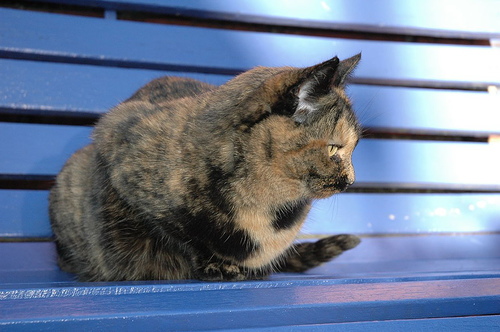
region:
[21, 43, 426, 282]
cat sitting on a bench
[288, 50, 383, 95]
two pointy ears on the head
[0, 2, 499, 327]
blue paint on the bench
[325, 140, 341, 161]
small yellow eye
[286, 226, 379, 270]
black stripes on the tail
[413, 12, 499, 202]
light shining on the bench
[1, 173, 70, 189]
space between the wooden slabs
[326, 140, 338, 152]
black line on the eyeball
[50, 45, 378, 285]
cat's body is covered in fur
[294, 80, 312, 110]
light hair in the ear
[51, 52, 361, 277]
a cat is sitting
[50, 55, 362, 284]
the cat is furry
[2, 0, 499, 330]
the bench is wood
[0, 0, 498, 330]
bench is painted blue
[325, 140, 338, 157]
eye of a cat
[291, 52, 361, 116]
ears are pointed forward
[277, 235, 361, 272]
tail of a cat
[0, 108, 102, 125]
gap in the bench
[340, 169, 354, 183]
nose of a cat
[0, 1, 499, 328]
A blue bench with a cat sitting on it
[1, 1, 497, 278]
The back support of the bench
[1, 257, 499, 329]
The seat of the bench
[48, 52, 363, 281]
A brown and black cat sitting on a bench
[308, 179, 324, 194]
A cat's cheek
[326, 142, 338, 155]
A cat's eye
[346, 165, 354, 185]
A cat's nose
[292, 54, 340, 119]
A cat's ear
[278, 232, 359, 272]
A cat's tail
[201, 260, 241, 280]
A cat's paw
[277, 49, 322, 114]
ear of the cat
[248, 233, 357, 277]
tail of the cat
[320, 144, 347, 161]
eye of the cat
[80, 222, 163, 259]
fur of the cat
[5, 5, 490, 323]
a scene outside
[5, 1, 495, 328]
a blue park bench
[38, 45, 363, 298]
a black and tan cat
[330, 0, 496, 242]
a bright spot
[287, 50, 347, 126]
a cat's ear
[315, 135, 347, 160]
a cat's eye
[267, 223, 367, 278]
a cat's tail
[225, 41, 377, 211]
a cat's head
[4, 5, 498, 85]
a blue plank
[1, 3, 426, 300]
the cat is on a bench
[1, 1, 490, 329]
the bench is blue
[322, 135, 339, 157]
this is the cat's eye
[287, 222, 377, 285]
this is the cat's tail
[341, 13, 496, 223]
the sunlight is shining brightly on the bench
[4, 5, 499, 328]
the bench is made of wood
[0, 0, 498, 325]
the bench beams are painted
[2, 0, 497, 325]
a wooden bench that has been painted blue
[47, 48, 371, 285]
cat looking down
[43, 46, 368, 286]
cat resting on bench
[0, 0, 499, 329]
bench supporting a cat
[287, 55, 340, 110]
ear belongs to cat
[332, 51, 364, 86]
ear belongs to cat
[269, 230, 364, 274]
tail belongs to cat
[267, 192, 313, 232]
black spot on cat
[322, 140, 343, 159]
eye on face of cat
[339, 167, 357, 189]
nose belongs to cat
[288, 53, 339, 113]
The ear of a cat